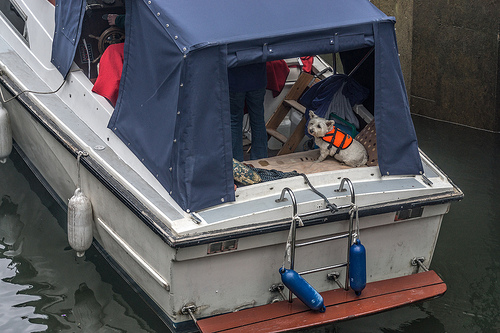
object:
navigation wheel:
[88, 25, 125, 63]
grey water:
[452, 230, 499, 311]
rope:
[348, 202, 359, 238]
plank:
[191, 267, 449, 333]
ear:
[325, 120, 335, 128]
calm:
[49, 293, 106, 331]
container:
[67, 188, 94, 258]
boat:
[0, 0, 463, 330]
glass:
[0, 0, 28, 47]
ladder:
[246, 71, 345, 159]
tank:
[278, 267, 326, 313]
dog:
[307, 110, 368, 168]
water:
[0, 111, 499, 332]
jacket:
[321, 125, 353, 157]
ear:
[308, 110, 318, 120]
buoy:
[349, 238, 366, 296]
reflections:
[0, 111, 499, 333]